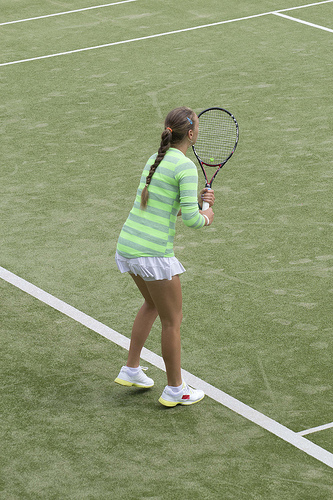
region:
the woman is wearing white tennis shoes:
[160, 379, 205, 415]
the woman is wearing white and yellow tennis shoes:
[159, 386, 203, 406]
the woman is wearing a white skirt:
[119, 249, 178, 280]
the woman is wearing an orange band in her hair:
[165, 122, 172, 134]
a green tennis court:
[8, 364, 94, 461]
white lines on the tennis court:
[236, 403, 291, 433]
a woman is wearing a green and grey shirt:
[117, 154, 195, 251]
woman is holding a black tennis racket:
[196, 105, 234, 204]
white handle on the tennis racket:
[197, 191, 218, 216]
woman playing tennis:
[116, 105, 219, 400]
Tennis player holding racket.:
[111, 97, 205, 410]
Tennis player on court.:
[99, 97, 238, 406]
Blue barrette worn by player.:
[184, 111, 195, 125]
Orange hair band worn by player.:
[166, 122, 173, 131]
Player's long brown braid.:
[137, 127, 176, 204]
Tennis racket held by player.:
[191, 95, 239, 233]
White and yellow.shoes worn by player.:
[110, 355, 206, 417]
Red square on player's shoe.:
[178, 391, 188, 399]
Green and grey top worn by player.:
[111, 147, 205, 258]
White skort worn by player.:
[112, 251, 185, 281]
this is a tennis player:
[88, 104, 240, 431]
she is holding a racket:
[189, 130, 229, 229]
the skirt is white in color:
[142, 258, 169, 277]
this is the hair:
[134, 130, 173, 191]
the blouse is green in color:
[159, 165, 183, 208]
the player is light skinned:
[192, 130, 196, 137]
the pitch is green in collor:
[225, 214, 313, 367]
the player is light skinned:
[158, 283, 177, 304]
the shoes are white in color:
[156, 387, 204, 405]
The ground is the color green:
[19, 69, 84, 174]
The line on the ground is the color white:
[22, 21, 266, 68]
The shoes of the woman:
[106, 356, 208, 411]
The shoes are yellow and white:
[112, 360, 213, 410]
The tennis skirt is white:
[107, 231, 187, 282]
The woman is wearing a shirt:
[112, 146, 210, 265]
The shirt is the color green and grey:
[112, 144, 209, 259]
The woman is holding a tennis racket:
[189, 96, 239, 224]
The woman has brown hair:
[134, 96, 203, 212]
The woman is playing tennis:
[110, 84, 269, 423]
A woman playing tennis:
[112, 106, 204, 407]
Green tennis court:
[3, 1, 331, 497]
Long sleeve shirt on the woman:
[116, 148, 205, 257]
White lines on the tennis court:
[1, 2, 331, 469]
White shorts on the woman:
[115, 251, 186, 280]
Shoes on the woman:
[114, 365, 204, 407]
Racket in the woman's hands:
[191, 107, 239, 209]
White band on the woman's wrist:
[204, 212, 209, 225]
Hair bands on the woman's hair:
[144, 126, 173, 187]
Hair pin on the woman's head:
[186, 116, 194, 125]